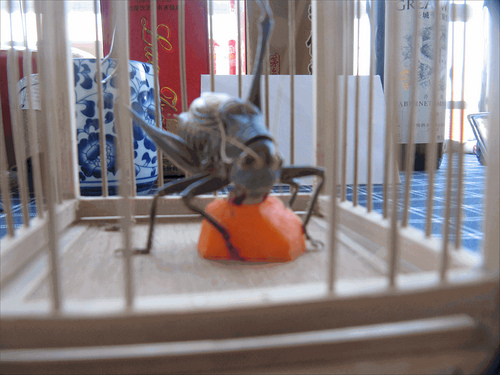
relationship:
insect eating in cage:
[128, 85, 326, 192] [257, 30, 420, 56]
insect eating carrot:
[128, 85, 326, 192] [209, 210, 318, 253]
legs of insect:
[162, 175, 203, 265] [128, 85, 326, 192]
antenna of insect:
[209, 110, 281, 177] [128, 85, 326, 192]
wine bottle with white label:
[420, 147, 427, 166] [376, 2, 453, 143]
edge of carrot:
[279, 227, 304, 251] [209, 210, 318, 253]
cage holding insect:
[257, 30, 420, 56] [128, 85, 326, 192]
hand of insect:
[217, 218, 230, 259] [128, 85, 326, 192]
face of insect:
[226, 145, 271, 201] [128, 85, 326, 192]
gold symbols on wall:
[296, 5, 324, 76] [249, 8, 259, 22]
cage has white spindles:
[257, 30, 420, 56] [309, 14, 333, 62]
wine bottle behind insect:
[420, 147, 427, 166] [128, 85, 326, 192]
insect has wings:
[128, 85, 326, 192] [180, 118, 208, 161]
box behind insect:
[98, 0, 222, 153] [128, 85, 326, 192]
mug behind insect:
[75, 89, 101, 160] [128, 85, 326, 192]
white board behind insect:
[203, 74, 385, 164] [128, 85, 326, 192]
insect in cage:
[128, 85, 326, 192] [257, 30, 420, 56]